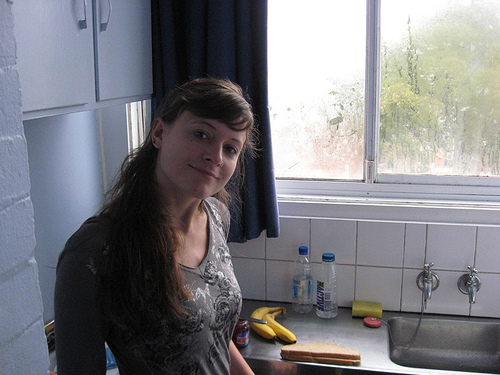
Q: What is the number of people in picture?
A: One.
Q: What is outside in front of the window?
A: Trees.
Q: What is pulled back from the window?
A: Curtain.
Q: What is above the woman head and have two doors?
A: Cabinet.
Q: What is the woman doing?
A: Standing by the counter.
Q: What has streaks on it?
A: Window.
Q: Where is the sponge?
A: On the counter.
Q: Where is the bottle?
A: On the counter.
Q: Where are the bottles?
A: On the counter.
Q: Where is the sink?
A: In the counter.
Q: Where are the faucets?
A: On the wall.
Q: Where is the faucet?
A: On the wall.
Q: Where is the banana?
A: On the counter.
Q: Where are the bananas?
A: On the counter.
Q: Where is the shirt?
A: On the woman.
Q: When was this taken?
A: During the day.